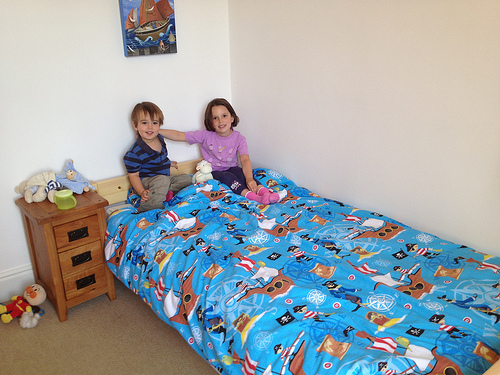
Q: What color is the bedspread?
A: Blue.